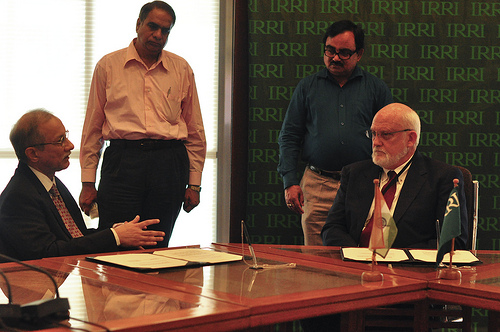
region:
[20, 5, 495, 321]
The men are having a meeting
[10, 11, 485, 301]
The men are meeting a room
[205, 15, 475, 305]
The men are listening very closely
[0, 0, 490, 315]
Some men are in a staff meeting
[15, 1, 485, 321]
The men are working in daytime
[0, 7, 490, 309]
Some men are working in the city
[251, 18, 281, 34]
company on the board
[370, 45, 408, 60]
company on the board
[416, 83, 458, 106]
company on the board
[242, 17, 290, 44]
company on the board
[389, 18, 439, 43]
company on the board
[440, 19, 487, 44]
company on the board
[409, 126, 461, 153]
company on the board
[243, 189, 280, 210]
company on the board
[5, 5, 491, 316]
The men are having a meeting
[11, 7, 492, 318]
The men are doing their work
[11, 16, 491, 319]
Some men are having a discussion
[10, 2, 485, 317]
Two men are seated at a table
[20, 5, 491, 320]
Two men are standing up straight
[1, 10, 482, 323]
Four men are having a talk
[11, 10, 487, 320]
The men are talking in an office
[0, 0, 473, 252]
four men in an office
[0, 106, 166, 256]
man wearing a suit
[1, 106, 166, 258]
man wearing a tie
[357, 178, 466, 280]
two flags on top of table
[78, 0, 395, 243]
two men standing up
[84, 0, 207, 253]
man wearing a pink shirt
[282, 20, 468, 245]
two men wearing glasses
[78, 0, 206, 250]
man has pen in pocket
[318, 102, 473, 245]
man has white beard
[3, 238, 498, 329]
table has wood and glass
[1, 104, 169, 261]
Man is wearing a suit and tie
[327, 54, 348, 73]
Black mustache on man's face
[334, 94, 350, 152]
Three buttons on a blue shirt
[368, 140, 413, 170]
White beard on a man's face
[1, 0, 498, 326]
Four men are conducting a meeting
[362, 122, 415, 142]
A pair of eyeglasses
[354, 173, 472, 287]
Two flags on the table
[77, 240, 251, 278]
An open booklet with white papers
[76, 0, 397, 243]
Two men are standing up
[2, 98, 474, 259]
Two men are sitting down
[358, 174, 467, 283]
two flags on the table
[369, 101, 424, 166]
man is bald on the top of his head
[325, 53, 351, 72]
man has a mustache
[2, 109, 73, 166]
man is wearing glasses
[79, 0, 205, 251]
man is standing in front of the window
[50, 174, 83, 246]
man is wearing a tie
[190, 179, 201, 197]
man has a watch on wrist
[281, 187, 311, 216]
man is wearing a ring on his finger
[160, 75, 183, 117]
pen in the pocket of the shirt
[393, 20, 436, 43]
IRRI written on the wall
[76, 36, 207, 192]
Peach colored shirt on the man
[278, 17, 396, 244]
Man wearing green shirt and khaki pants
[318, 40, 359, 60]
Glasses over man's eyees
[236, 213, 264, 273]
Pen in holder on the table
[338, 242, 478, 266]
Notebook and papers in front of the man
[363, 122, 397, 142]
Glasses over man's eyes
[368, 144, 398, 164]
Beard and mustache on man's face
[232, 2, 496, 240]
The letters IRRI repeated on the wall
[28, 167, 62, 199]
shirt worn by human